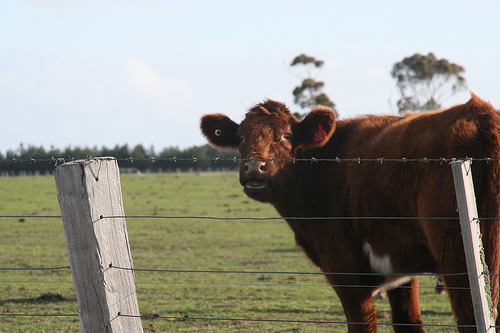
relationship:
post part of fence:
[54, 156, 144, 332] [0, 154, 499, 332]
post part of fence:
[450, 158, 496, 332] [0, 154, 499, 332]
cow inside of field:
[200, 91, 499, 331] [0, 171, 459, 332]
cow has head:
[200, 91, 499, 331] [199, 97, 336, 203]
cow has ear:
[200, 91, 499, 331] [199, 113, 240, 151]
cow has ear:
[200, 91, 499, 331] [297, 104, 337, 150]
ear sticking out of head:
[199, 113, 240, 151] [199, 97, 336, 203]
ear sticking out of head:
[297, 104, 337, 150] [199, 97, 336, 203]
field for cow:
[0, 171, 459, 332] [200, 91, 499, 331]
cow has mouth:
[200, 91, 499, 331] [244, 176, 268, 189]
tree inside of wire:
[116, 142, 132, 174] [1, 154, 500, 164]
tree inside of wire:
[130, 144, 148, 174] [1, 154, 500, 164]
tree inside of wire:
[157, 145, 181, 173] [1, 154, 500, 164]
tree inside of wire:
[290, 53, 339, 121] [1, 154, 500, 164]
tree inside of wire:
[390, 52, 466, 111] [1, 154, 500, 164]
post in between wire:
[54, 156, 144, 332] [1, 154, 500, 164]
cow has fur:
[200, 91, 499, 331] [200, 91, 498, 331]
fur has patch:
[200, 91, 498, 331] [362, 240, 411, 296]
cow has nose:
[200, 91, 499, 331] [243, 160, 268, 176]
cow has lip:
[200, 91, 499, 331] [244, 176, 266, 183]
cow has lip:
[200, 91, 499, 331] [244, 181, 267, 190]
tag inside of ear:
[313, 123, 328, 143] [297, 104, 337, 150]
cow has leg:
[200, 91, 499, 331] [386, 276, 425, 332]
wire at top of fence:
[1, 154, 500, 164] [0, 154, 499, 332]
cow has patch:
[200, 91, 499, 331] [362, 240, 411, 296]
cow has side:
[200, 91, 499, 331] [255, 92, 499, 331]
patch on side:
[362, 240, 411, 296] [255, 92, 499, 331]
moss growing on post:
[475, 219, 495, 318] [450, 158, 496, 332]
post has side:
[450, 158, 496, 332] [460, 158, 496, 332]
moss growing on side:
[475, 219, 495, 318] [460, 158, 496, 332]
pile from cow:
[37, 291, 66, 301] [200, 91, 499, 331]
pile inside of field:
[37, 291, 66, 301] [0, 171, 459, 332]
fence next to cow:
[0, 154, 499, 332] [200, 91, 499, 331]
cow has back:
[200, 91, 499, 331] [296, 89, 499, 145]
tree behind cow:
[390, 52, 466, 111] [200, 91, 499, 331]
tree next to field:
[116, 142, 132, 174] [0, 171, 459, 332]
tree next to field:
[130, 144, 148, 174] [0, 171, 459, 332]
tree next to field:
[157, 145, 181, 173] [0, 171, 459, 332]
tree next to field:
[290, 53, 339, 121] [0, 171, 459, 332]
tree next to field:
[390, 52, 466, 111] [0, 171, 459, 332]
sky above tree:
[1, 1, 500, 159] [390, 52, 466, 111]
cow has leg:
[200, 91, 499, 331] [312, 230, 377, 332]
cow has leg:
[200, 91, 499, 331] [417, 190, 499, 331]